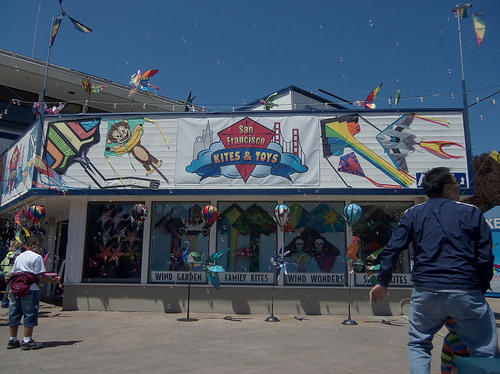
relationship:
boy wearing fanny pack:
[0, 226, 62, 357] [7, 273, 41, 293]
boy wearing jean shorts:
[0, 226, 62, 357] [7, 290, 41, 327]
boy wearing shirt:
[0, 226, 62, 357] [13, 251, 50, 292]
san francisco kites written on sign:
[212, 115, 281, 168] [5, 108, 476, 209]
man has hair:
[372, 162, 496, 373] [418, 168, 454, 199]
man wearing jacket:
[372, 162, 496, 373] [381, 196, 493, 298]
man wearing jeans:
[372, 162, 496, 373] [407, 286, 499, 373]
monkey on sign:
[105, 114, 164, 181] [5, 108, 476, 209]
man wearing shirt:
[372, 162, 496, 373] [13, 251, 50, 292]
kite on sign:
[318, 119, 414, 192] [5, 108, 476, 209]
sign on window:
[216, 201, 275, 286] [212, 201, 279, 287]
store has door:
[11, 108, 484, 341] [37, 218, 73, 308]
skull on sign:
[312, 236, 327, 258] [283, 197, 349, 292]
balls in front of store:
[25, 199, 48, 230] [11, 108, 484, 341]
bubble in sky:
[366, 16, 378, 32] [3, 5, 500, 160]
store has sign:
[11, 108, 484, 341] [5, 108, 476, 209]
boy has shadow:
[0, 226, 62, 357] [25, 335, 88, 355]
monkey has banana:
[105, 114, 164, 181] [105, 126, 151, 158]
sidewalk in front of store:
[12, 296, 488, 372] [11, 108, 484, 341]